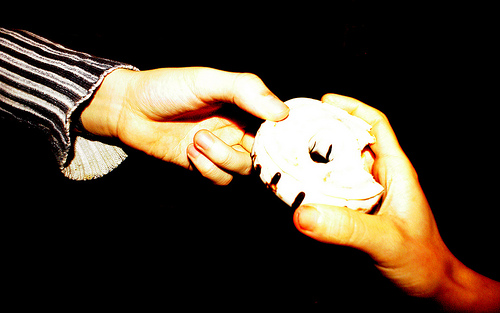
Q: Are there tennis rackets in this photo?
A: No, there are no tennis rackets.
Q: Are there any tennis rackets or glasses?
A: No, there are no tennis rackets or glasses.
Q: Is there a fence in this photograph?
A: No, there are no fences.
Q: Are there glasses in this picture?
A: No, there are no glasses.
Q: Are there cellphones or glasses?
A: No, there are no glasses or cellphones.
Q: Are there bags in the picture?
A: No, there are no bags.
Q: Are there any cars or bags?
A: No, there are no bags or cars.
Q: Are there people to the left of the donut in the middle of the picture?
A: Yes, there is a person to the left of the doughnut.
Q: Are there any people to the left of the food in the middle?
A: Yes, there is a person to the left of the doughnut.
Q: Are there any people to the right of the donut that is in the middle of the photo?
A: No, the person is to the left of the donut.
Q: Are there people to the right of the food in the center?
A: No, the person is to the left of the donut.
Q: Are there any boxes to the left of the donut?
A: No, there is a person to the left of the donut.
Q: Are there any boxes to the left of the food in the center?
A: No, there is a person to the left of the donut.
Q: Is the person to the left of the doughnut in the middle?
A: Yes, the person is to the left of the donut.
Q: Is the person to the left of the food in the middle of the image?
A: Yes, the person is to the left of the donut.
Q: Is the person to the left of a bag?
A: No, the person is to the left of the donut.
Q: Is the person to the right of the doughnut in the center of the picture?
A: No, the person is to the left of the doughnut.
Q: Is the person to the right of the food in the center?
A: No, the person is to the left of the doughnut.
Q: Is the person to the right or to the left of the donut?
A: The person is to the left of the donut.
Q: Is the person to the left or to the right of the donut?
A: The person is to the left of the donut.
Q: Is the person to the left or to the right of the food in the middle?
A: The person is to the left of the donut.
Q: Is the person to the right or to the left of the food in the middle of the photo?
A: The person is to the left of the donut.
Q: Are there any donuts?
A: Yes, there is a donut.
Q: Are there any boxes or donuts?
A: Yes, there is a donut.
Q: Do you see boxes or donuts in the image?
A: Yes, there is a donut.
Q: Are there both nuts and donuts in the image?
A: No, there is a donut but no nuts.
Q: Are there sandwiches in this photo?
A: No, there are no sandwiches.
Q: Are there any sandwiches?
A: No, there are no sandwiches.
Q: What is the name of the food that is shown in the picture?
A: The food is a donut.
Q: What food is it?
A: The food is a donut.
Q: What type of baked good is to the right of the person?
A: The food is a donut.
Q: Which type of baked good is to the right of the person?
A: The food is a donut.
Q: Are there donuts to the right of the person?
A: Yes, there is a donut to the right of the person.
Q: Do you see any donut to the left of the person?
A: No, the donut is to the right of the person.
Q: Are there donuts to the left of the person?
A: No, the donut is to the right of the person.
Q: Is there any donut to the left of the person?
A: No, the donut is to the right of the person.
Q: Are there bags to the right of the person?
A: No, there is a donut to the right of the person.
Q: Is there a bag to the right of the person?
A: No, there is a donut to the right of the person.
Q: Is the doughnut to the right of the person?
A: Yes, the doughnut is to the right of the person.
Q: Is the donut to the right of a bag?
A: No, the donut is to the right of the person.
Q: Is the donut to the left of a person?
A: No, the donut is to the right of a person.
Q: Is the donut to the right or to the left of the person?
A: The donut is to the right of the person.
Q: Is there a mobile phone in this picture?
A: No, there are no cell phones.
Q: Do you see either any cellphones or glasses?
A: No, there are no cellphones or glasses.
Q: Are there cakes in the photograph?
A: No, there are no cakes.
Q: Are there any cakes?
A: No, there are no cakes.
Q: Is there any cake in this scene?
A: No, there are no cakes.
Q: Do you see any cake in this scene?
A: No, there are no cakes.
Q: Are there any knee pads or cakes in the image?
A: No, there are no cakes or knee pads.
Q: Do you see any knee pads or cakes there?
A: No, there are no cakes or knee pads.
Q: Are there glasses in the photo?
A: No, there are no glasses.